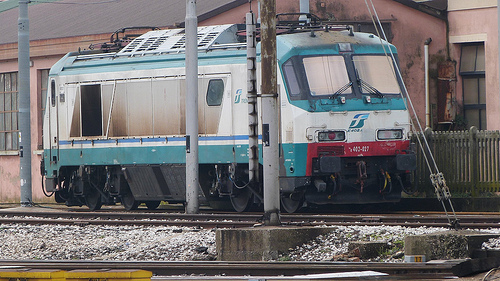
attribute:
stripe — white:
[44, 61, 402, 139]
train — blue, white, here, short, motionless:
[38, 15, 407, 203]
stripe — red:
[306, 139, 407, 181]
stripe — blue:
[54, 49, 250, 72]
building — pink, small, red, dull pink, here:
[2, 1, 498, 210]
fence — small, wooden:
[402, 128, 497, 207]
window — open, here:
[77, 88, 108, 135]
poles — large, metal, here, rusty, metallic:
[181, 1, 286, 219]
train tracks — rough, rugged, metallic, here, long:
[4, 198, 498, 241]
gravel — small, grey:
[3, 210, 498, 280]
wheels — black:
[76, 167, 259, 212]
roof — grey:
[3, 1, 240, 29]